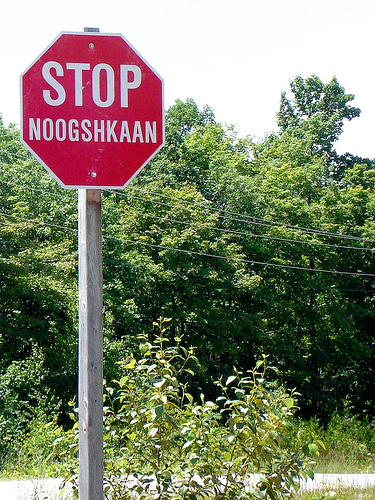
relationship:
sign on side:
[16, 24, 164, 191] [6, 380, 374, 492]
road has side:
[4, 455, 373, 495] [6, 380, 374, 492]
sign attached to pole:
[16, 24, 164, 191] [76, 189, 110, 498]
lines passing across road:
[0, 173, 374, 279] [4, 455, 373, 495]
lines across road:
[0, 173, 374, 279] [4, 455, 373, 495]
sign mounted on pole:
[13, 24, 181, 191] [76, 189, 110, 498]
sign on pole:
[13, 24, 181, 191] [76, 189, 110, 498]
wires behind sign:
[0, 170, 373, 282] [13, 24, 181, 191]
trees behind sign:
[3, 73, 374, 496] [13, 24, 181, 191]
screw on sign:
[85, 41, 100, 53] [13, 24, 181, 191]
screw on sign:
[88, 168, 100, 182] [13, 24, 181, 191]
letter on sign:
[103, 117, 126, 145] [13, 24, 181, 191]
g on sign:
[68, 118, 79, 147] [13, 24, 181, 191]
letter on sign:
[65, 57, 92, 114] [13, 24, 181, 191]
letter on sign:
[117, 61, 144, 109] [13, 24, 181, 191]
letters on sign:
[26, 60, 162, 147] [13, 24, 181, 191]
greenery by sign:
[28, 323, 328, 498] [13, 24, 181, 191]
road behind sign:
[4, 455, 373, 495] [13, 24, 181, 191]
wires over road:
[0, 170, 373, 282] [4, 455, 373, 495]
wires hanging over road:
[0, 170, 373, 282] [4, 455, 373, 495]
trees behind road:
[3, 71, 373, 421] [4, 455, 373, 495]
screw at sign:
[88, 168, 100, 182] [13, 24, 181, 191]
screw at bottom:
[88, 168, 100, 182] [63, 156, 128, 188]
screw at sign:
[85, 41, 100, 53] [13, 24, 181, 191]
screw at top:
[85, 41, 100, 53] [63, 38, 121, 63]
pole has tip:
[76, 189, 110, 498] [82, 27, 100, 34]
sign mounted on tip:
[13, 24, 181, 191] [82, 27, 100, 34]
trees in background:
[3, 71, 373, 421] [7, 8, 374, 471]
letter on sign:
[92, 117, 106, 144] [13, 24, 181, 191]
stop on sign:
[39, 58, 147, 112] [13, 24, 181, 191]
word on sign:
[22, 115, 163, 145] [13, 24, 181, 191]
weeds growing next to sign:
[0, 410, 364, 500] [13, 24, 181, 191]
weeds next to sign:
[0, 410, 364, 500] [13, 24, 181, 191]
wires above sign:
[0, 170, 373, 282] [13, 24, 181, 191]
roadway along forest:
[4, 469, 374, 493] [4, 67, 375, 434]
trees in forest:
[3, 71, 373, 421] [4, 67, 375, 434]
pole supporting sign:
[76, 189, 110, 498] [13, 24, 181, 191]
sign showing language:
[13, 24, 181, 191] [24, 61, 158, 140]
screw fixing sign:
[85, 41, 100, 53] [13, 24, 181, 191]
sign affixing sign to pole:
[13, 24, 181, 191] [76, 189, 110, 498]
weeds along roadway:
[28, 312, 331, 499] [4, 469, 374, 493]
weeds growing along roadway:
[28, 312, 331, 499] [4, 469, 374, 493]